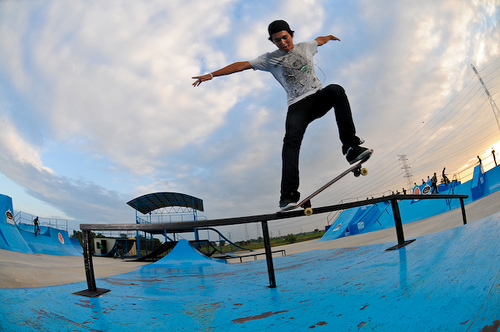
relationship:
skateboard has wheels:
[281, 147, 371, 211] [303, 205, 311, 216]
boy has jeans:
[189, 20, 367, 201] [280, 85, 362, 202]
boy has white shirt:
[189, 20, 367, 201] [249, 40, 320, 101]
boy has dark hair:
[189, 20, 367, 201] [266, 24, 297, 36]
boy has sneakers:
[189, 20, 367, 201] [345, 143, 371, 161]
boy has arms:
[189, 20, 367, 201] [192, 62, 253, 83]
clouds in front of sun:
[375, 6, 491, 72] [456, 138, 497, 172]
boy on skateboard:
[189, 20, 367, 201] [281, 147, 371, 211]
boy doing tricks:
[189, 20, 367, 201] [277, 107, 378, 222]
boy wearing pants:
[189, 20, 367, 201] [280, 85, 362, 202]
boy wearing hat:
[189, 20, 367, 201] [269, 20, 290, 31]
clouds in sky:
[375, 6, 491, 72] [11, 9, 186, 185]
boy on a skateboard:
[189, 20, 367, 201] [281, 147, 371, 211]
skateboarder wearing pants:
[189, 20, 367, 201] [280, 85, 362, 202]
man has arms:
[189, 20, 367, 201] [192, 62, 253, 83]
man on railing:
[189, 20, 367, 201] [75, 196, 470, 239]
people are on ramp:
[403, 168, 454, 194] [333, 185, 482, 226]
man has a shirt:
[189, 20, 367, 201] [249, 40, 320, 101]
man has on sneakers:
[189, 20, 367, 201] [345, 143, 371, 161]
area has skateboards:
[2, 192, 498, 324] [281, 147, 371, 211]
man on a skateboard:
[189, 20, 367, 201] [281, 147, 371, 211]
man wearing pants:
[189, 20, 367, 201] [280, 85, 362, 202]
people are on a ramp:
[403, 168, 454, 194] [333, 185, 482, 226]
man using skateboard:
[189, 20, 367, 201] [281, 147, 371, 211]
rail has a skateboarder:
[75, 196, 470, 239] [189, 20, 367, 201]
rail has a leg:
[80, 222, 437, 282] [383, 196, 413, 256]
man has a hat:
[189, 20, 367, 201] [269, 20, 290, 31]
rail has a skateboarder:
[77, 191, 468, 279] [189, 20, 367, 201]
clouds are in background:
[375, 6, 491, 72] [7, 4, 193, 175]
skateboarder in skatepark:
[189, 20, 367, 201] [2, 192, 498, 324]